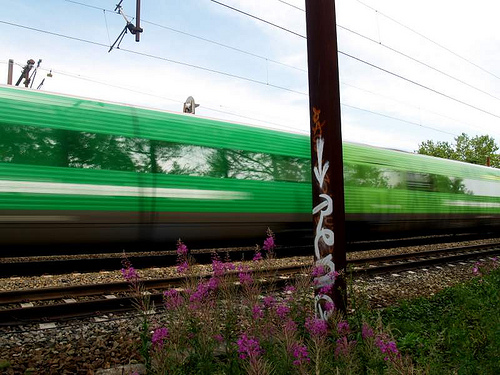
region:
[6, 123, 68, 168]
glass window on train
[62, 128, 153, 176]
glass window on train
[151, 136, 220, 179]
glass window on train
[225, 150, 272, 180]
glass window on train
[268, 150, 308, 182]
glass window on train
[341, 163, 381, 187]
glass window on train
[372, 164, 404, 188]
glass window on train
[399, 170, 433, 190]
glass window on train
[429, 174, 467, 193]
glass window on train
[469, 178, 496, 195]
glass window on train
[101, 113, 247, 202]
green train in photo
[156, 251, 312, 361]
purple flowers in photo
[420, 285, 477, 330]
grass next to train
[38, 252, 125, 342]
track next to train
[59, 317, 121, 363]
rocks next to train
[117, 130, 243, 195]
side of the train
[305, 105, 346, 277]
writing on the pole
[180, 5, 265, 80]
wires above the land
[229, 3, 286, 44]
cloud in the sky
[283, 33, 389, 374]
the pole is brown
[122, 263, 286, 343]
flowers are by the grass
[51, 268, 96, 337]
rocks are by the train tracks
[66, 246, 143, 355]
the train tracks are brown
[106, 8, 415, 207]
the power lines are over the train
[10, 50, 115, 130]
the power lines are over the train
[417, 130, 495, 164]
the trees are behind the train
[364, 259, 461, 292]
the rocks are by the train track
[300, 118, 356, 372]
grafitti is on the pole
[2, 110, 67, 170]
window on passenger train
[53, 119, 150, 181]
window on passenger train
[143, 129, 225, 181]
window on passenger train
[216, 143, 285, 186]
window on passenger train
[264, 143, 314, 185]
window on passenger train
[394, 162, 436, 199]
window on passenger train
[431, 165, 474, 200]
window on passenger train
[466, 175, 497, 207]
window on passenger train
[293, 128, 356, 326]
white letters on pole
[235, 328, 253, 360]
pink flower by the railroad track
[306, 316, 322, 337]
pink flower by the railroad track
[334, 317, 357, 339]
pink flower by the railroad track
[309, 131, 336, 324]
graffiti is on pole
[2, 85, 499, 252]
train on tracks is green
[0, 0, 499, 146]
wires hang above passing train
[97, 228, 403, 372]
flowers next to tracks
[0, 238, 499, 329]
tracks next to train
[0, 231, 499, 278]
shadow cast by train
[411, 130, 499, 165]
trees behind train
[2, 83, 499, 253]
train in front of trees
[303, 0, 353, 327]
pole in front of train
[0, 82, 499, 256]
train behind pole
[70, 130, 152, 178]
a window on a train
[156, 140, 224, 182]
a window on a train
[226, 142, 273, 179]
a window on a train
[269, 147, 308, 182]
a window on a train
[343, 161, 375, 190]
a window on a train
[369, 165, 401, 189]
a window on a train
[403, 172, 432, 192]
a window on a train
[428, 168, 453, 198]
a window on a train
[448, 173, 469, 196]
a window on a train